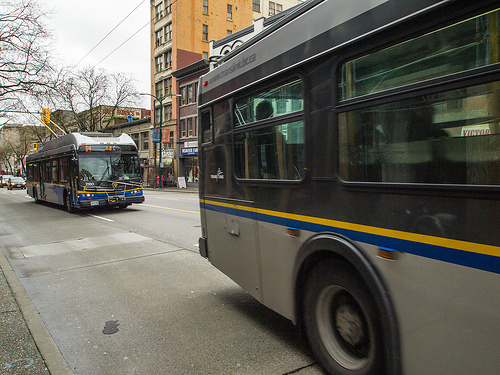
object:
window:
[177, 85, 187, 102]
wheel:
[65, 189, 77, 212]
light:
[374, 244, 398, 261]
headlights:
[77, 192, 95, 199]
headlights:
[130, 189, 142, 196]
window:
[185, 118, 192, 135]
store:
[150, 147, 177, 187]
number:
[2, 349, 36, 373]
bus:
[24, 130, 146, 214]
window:
[219, 73, 315, 183]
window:
[197, 108, 212, 146]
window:
[149, 21, 178, 50]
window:
[174, 79, 196, 106]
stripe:
[198, 193, 500, 273]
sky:
[26, 3, 137, 102]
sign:
[162, 127, 170, 141]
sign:
[152, 130, 161, 143]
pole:
[157, 97, 163, 182]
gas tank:
[224, 208, 246, 235]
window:
[337, 10, 498, 180]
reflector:
[375, 246, 399, 260]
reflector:
[285, 228, 300, 238]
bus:
[197, 0, 499, 375]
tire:
[293, 253, 388, 374]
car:
[6, 177, 26, 190]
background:
[2, 0, 298, 219]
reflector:
[77, 192, 94, 198]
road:
[2, 177, 342, 362]